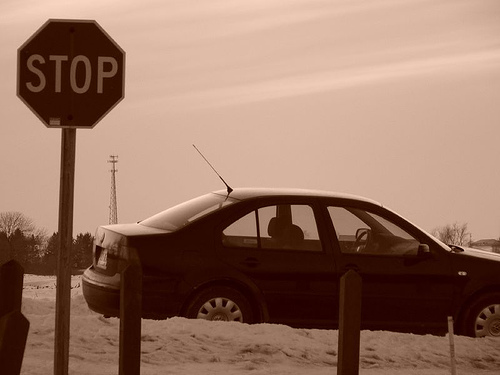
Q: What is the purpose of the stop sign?
A: To stop cars.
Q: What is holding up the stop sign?
A: A pole.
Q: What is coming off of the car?
A: An antenna.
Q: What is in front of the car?
A: Small poles.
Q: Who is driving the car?
A: No one is driving the car.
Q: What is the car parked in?
A: The snow.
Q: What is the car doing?
A: The car is sitting.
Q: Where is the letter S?
A: On the stop sign.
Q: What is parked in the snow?
A: A car.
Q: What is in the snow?
A: The wood fence.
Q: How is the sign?
A: On a post.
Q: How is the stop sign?
A: Red and white.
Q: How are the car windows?
A: Clear.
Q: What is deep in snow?
A: The car.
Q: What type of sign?
A: Red and white.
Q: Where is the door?
A: On the car.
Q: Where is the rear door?
A: On the car.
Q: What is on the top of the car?
A: Rear antenna.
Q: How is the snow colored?
A: White.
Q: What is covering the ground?
A: Snow.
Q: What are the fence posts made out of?
A: Wood.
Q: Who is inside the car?
A: There is no one in the car.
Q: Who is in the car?
A: No one.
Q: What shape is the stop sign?
A: Octagonal.